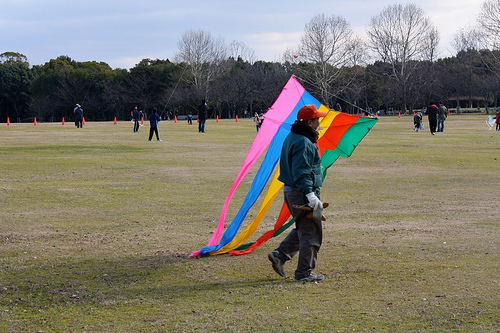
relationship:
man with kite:
[266, 104, 329, 280] [189, 74, 379, 258]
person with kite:
[494, 111, 500, 130] [488, 113, 497, 132]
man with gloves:
[266, 104, 329, 280] [306, 193, 325, 213]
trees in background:
[1, 49, 500, 121] [0, 1, 498, 155]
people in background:
[68, 95, 499, 140] [0, 1, 498, 155]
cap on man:
[296, 104, 328, 119] [266, 104, 329, 280]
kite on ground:
[189, 74, 379, 258] [4, 232, 499, 331]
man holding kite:
[266, 104, 329, 280] [189, 74, 379, 258]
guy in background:
[197, 96, 210, 132] [0, 1, 498, 155]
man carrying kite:
[266, 104, 329, 280] [189, 74, 379, 258]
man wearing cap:
[266, 104, 329, 280] [296, 104, 328, 119]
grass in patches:
[46, 259, 72, 277] [48, 234, 181, 323]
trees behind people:
[1, 49, 500, 121] [68, 95, 499, 140]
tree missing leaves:
[175, 29, 252, 120] [142, 59, 168, 68]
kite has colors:
[189, 74, 379, 258] [260, 123, 356, 149]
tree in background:
[175, 29, 252, 120] [0, 1, 498, 155]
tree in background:
[366, 1, 441, 114] [0, 1, 498, 155]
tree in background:
[286, 14, 366, 115] [0, 1, 498, 155]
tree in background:
[445, 1, 499, 104] [0, 1, 498, 155]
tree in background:
[0, 52, 34, 122] [0, 1, 498, 155]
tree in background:
[34, 68, 114, 122] [0, 1, 498, 155]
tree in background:
[252, 62, 293, 115] [0, 1, 498, 155]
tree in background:
[367, 62, 405, 109] [0, 1, 498, 155]